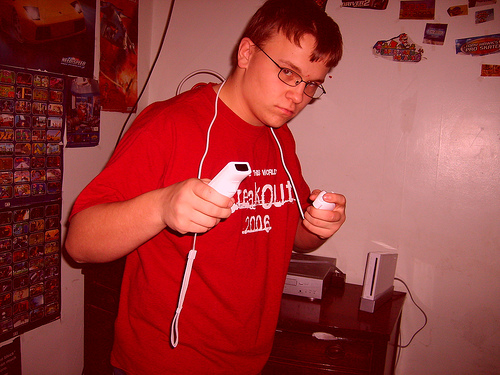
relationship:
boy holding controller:
[229, 17, 338, 151] [183, 153, 268, 239]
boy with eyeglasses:
[229, 17, 338, 151] [265, 50, 334, 105]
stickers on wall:
[338, 4, 499, 95] [104, 17, 473, 303]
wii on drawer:
[349, 244, 407, 322] [286, 297, 386, 371]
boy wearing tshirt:
[229, 17, 338, 151] [121, 106, 285, 291]